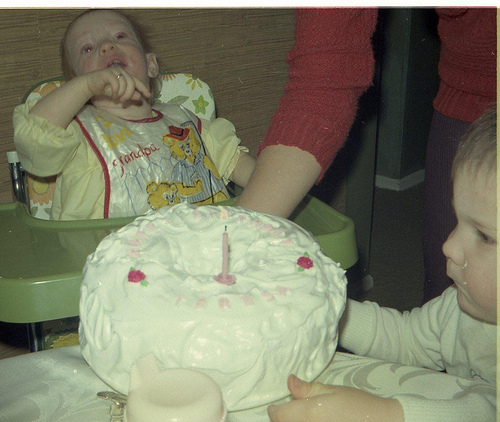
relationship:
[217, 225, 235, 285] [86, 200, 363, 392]
pink candle on cake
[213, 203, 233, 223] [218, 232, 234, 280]
flame on candle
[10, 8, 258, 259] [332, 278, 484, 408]
baby wearing sweatshirt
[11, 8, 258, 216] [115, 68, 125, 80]
baby with ring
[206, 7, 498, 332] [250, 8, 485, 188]
adult has sweater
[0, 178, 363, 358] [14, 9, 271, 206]
chair with baby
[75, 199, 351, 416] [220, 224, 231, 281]
cake with candle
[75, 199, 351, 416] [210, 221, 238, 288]
cake with candle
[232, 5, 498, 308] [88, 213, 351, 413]
person holding cake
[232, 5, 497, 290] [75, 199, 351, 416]
person holding cake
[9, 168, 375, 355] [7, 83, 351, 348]
tray on chair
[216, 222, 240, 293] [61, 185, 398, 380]
candle on cake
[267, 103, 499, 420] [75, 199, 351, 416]
baby touching cake